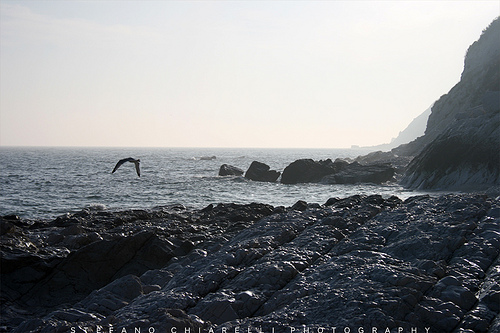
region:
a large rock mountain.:
[270, 18, 497, 184]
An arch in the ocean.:
[110, 150, 152, 185]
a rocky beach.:
[0, 192, 498, 332]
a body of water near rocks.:
[0, 145, 457, 203]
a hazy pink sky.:
[3, 0, 497, 151]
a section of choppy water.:
[43, 164, 75, 194]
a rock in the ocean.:
[213, 152, 248, 187]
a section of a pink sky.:
[119, 125, 162, 140]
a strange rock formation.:
[103, 155, 160, 181]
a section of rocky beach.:
[325, 232, 400, 285]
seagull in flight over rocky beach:
[110, 150, 145, 177]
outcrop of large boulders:
[213, 154, 416, 188]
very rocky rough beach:
[11, 194, 498, 331]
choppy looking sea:
[0, 136, 478, 205]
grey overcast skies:
[0, 0, 497, 147]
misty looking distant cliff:
[378, 96, 431, 149]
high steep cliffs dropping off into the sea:
[407, 16, 498, 195]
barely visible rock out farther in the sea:
[199, 153, 216, 162]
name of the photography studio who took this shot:
[68, 322, 464, 332]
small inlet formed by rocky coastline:
[275, 181, 495, 201]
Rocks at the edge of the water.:
[0, 150, 495, 330]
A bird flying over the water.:
[105, 150, 147, 178]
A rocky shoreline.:
[5, 106, 486, 321]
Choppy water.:
[10, 145, 396, 200]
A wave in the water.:
[173, 148, 223, 163]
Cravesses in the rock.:
[10, 205, 475, 330]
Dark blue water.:
[5, 146, 420, 206]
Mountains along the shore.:
[385, 30, 495, 193]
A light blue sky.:
[0, 30, 485, 145]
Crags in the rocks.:
[2, 195, 497, 330]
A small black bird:
[102, 153, 153, 180]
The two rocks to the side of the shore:
[217, 152, 284, 192]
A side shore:
[409, 18, 499, 196]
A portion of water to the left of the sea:
[0, 145, 75, 217]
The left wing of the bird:
[100, 152, 127, 180]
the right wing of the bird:
[132, 164, 149, 181]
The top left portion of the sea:
[0, 0, 144, 149]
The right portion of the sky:
[320, 0, 368, 150]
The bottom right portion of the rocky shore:
[387, 201, 499, 331]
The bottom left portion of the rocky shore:
[0, 229, 126, 331]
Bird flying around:
[89, 146, 163, 188]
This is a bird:
[101, 143, 156, 200]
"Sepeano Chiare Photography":
[42, 290, 451, 332]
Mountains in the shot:
[253, 5, 498, 197]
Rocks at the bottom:
[190, 141, 407, 193]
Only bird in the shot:
[91, 148, 155, 192]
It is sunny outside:
[24, 8, 389, 118]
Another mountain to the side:
[331, 78, 424, 150]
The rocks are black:
[169, 189, 478, 314]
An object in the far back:
[191, 150, 226, 165]